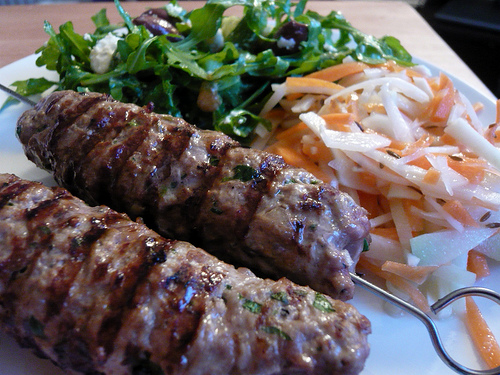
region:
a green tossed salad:
[31, 2, 409, 132]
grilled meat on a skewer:
[0, 76, 370, 371]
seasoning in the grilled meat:
[238, 272, 343, 347]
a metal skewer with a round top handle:
[356, 263, 496, 373]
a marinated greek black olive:
[135, 8, 195, 39]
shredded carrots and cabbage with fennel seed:
[271, 58, 496, 288]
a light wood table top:
[315, 2, 482, 107]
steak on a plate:
[1, 167, 274, 374]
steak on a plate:
[16, 77, 388, 299]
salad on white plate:
[44, 4, 364, 115]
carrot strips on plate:
[371, 180, 421, 222]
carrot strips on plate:
[292, 64, 354, 104]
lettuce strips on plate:
[175, 45, 230, 88]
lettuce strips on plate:
[96, 43, 160, 90]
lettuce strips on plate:
[8, 69, 52, 109]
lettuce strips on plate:
[41, 18, 88, 75]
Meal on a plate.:
[5, 5, 495, 366]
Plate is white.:
[0, 35, 491, 370]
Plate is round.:
[0, 30, 490, 365]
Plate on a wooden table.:
[1, 5, 496, 370]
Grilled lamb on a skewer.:
[0, 86, 370, 367]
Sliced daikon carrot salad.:
[290, 70, 495, 195]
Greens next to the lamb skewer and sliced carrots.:
[30, 2, 375, 93]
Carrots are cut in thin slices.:
[280, 63, 461, 193]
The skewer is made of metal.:
[365, 265, 496, 366]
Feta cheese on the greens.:
[83, 29, 128, 76]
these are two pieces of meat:
[0, 87, 375, 372]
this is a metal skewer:
[347, 265, 496, 372]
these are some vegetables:
[255, 50, 495, 367]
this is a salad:
[0, 1, 412, 138]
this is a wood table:
[6, 0, 496, 95]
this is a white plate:
[2, 18, 492, 372]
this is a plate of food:
[7, 1, 497, 371]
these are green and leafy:
[2, 5, 414, 141]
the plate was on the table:
[0, 11, 492, 371]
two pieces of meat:
[1, 83, 391, 373]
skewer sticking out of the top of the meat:
[327, 252, 498, 372]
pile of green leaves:
[0, 0, 425, 160]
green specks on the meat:
[232, 284, 354, 348]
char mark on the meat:
[223, 147, 295, 260]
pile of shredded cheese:
[252, 48, 498, 289]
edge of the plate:
[1, 46, 61, 80]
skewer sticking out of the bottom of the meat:
[0, 77, 35, 112]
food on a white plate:
[0, 2, 499, 372]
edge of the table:
[409, 0, 499, 102]